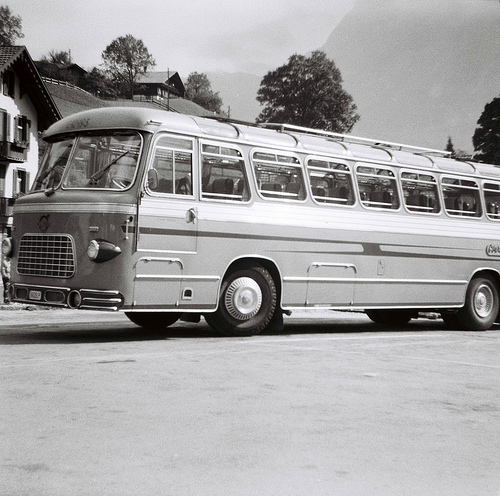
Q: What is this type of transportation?
A: A bus.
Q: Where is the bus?
A: Parked.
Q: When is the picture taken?
A: Daytime.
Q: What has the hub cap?
A: A tire.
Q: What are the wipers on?
A: A windshield.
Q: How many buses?
A: One.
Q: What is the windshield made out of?
A: Glass.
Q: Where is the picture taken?
A: In front of a house.